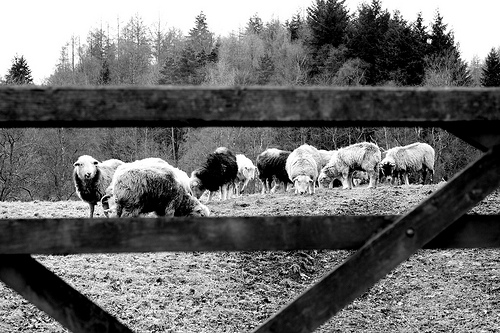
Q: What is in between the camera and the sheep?
A: Wooden fence.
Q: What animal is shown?
A: Sheep.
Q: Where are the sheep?
A: In a pen.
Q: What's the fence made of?
A: Wood.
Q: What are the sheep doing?
A: Eating.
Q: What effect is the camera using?
A: Black and white.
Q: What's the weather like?
A: Sunny.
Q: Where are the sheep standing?
A: Grass.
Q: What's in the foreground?
A: Fence.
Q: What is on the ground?
A: Feed.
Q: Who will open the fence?
A: A rancher.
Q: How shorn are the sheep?
A: Not at all.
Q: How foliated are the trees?
A: Nearly fully.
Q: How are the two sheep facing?
A: In opposite directions.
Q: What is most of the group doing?
A: Grazing.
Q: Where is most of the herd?
A: Further away from the gate.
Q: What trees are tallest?
A: The darker ones.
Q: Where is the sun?
A: Not visible.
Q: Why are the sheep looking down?
A: They are feeding.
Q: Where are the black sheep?
A: In the middle of the herd.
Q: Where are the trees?
A: Behind the sheep.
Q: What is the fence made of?
A: Wood.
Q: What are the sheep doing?
A: Grazing.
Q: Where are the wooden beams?
A: On the fence.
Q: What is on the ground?
A: Grass and dirt.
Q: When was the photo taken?
A: Daytime.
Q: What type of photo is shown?
A: Black and white.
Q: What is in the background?
A: Trees.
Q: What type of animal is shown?
A: Sheep.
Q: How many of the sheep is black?
A: Two.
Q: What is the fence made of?
A: Wood.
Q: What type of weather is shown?
A: Clear.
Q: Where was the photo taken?
A: On a farm.